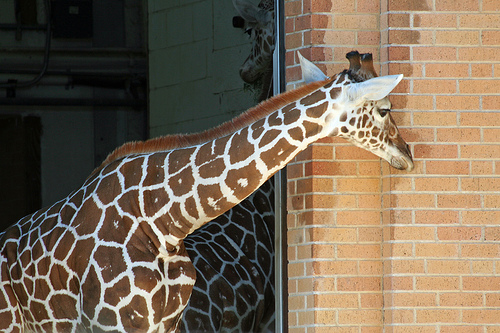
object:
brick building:
[280, 1, 497, 331]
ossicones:
[344, 51, 380, 82]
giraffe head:
[295, 49, 421, 173]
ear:
[347, 74, 403, 104]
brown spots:
[66, 233, 92, 274]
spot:
[327, 85, 343, 99]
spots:
[235, 177, 248, 187]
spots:
[208, 198, 219, 210]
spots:
[173, 176, 186, 187]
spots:
[95, 206, 130, 245]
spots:
[126, 309, 149, 322]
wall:
[0, 0, 285, 223]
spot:
[254, 126, 264, 138]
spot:
[288, 127, 304, 143]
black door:
[1, 115, 44, 230]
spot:
[186, 195, 200, 221]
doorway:
[1, 0, 283, 331]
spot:
[299, 90, 325, 106]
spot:
[141, 186, 171, 216]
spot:
[194, 134, 229, 165]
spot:
[164, 169, 193, 196]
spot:
[141, 151, 168, 188]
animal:
[0, 49, 411, 333]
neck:
[151, 96, 311, 238]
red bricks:
[411, 44, 459, 62]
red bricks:
[414, 208, 459, 223]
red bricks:
[412, 274, 462, 289]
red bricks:
[412, 176, 462, 193]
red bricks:
[335, 210, 382, 224]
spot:
[227, 127, 256, 164]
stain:
[284, 6, 344, 236]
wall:
[281, 0, 500, 333]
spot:
[167, 146, 192, 175]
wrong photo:
[0, 0, 499, 333]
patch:
[226, 160, 262, 199]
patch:
[196, 183, 231, 217]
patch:
[165, 170, 194, 196]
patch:
[96, 202, 131, 245]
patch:
[117, 296, 149, 330]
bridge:
[107, 95, 151, 111]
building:
[0, 0, 499, 333]